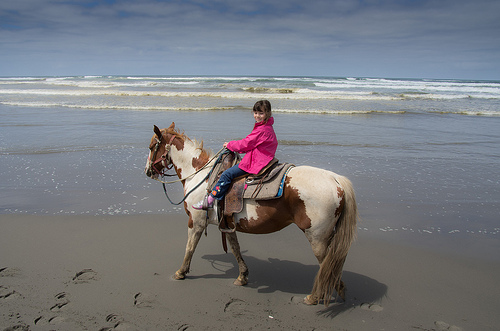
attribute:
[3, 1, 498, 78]
sky — cloudy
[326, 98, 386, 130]
lake — Section 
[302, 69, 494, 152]
lake — Section 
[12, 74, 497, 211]
lake — Section 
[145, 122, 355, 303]
horse — ON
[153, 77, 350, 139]
lake — Section 